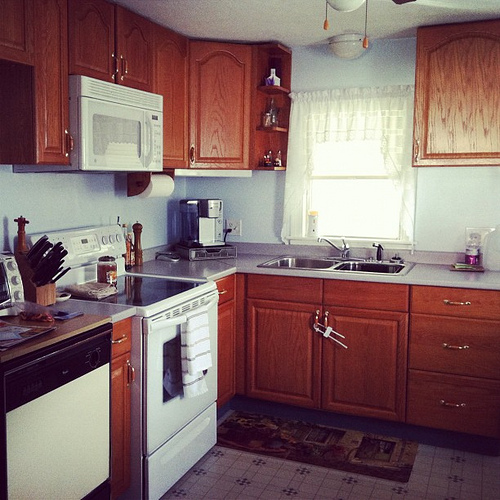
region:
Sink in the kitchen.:
[232, 217, 412, 317]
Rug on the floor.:
[211, 385, 415, 496]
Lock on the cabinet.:
[304, 294, 384, 383]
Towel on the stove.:
[163, 304, 243, 429]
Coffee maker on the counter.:
[163, 177, 258, 277]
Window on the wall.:
[260, 66, 457, 283]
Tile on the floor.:
[190, 431, 287, 493]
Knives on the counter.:
[13, 219, 79, 331]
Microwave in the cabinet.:
[54, 44, 283, 234]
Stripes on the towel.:
[155, 294, 261, 424]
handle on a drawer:
[435, 335, 472, 356]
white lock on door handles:
[307, 318, 352, 358]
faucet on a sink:
[314, 232, 370, 266]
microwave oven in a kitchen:
[62, 67, 170, 176]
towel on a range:
[175, 303, 218, 403]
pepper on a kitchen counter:
[129, 217, 149, 270]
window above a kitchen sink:
[276, 78, 427, 259]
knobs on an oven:
[97, 228, 127, 249]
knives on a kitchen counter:
[11, 233, 78, 308]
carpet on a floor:
[204, 404, 427, 490]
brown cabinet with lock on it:
[300, 298, 362, 350]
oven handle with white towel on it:
[166, 293, 231, 414]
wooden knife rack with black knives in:
[0, 247, 82, 322]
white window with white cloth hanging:
[293, 95, 408, 248]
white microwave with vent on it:
[23, 65, 179, 180]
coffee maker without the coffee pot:
[160, 187, 241, 277]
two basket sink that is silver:
[255, 220, 430, 283]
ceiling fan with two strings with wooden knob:
[323, 5, 393, 72]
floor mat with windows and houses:
[189, 368, 474, 493]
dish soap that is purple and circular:
[462, 218, 489, 275]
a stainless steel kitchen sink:
[260, 225, 411, 295]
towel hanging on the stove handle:
[162, 300, 229, 394]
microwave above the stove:
[68, 62, 175, 175]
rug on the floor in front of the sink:
[217, 390, 425, 495]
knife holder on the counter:
[15, 236, 73, 301]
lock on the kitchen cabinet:
[309, 301, 345, 357]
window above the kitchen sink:
[287, 81, 421, 246]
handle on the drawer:
[437, 334, 484, 362]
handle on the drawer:
[427, 392, 474, 428]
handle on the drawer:
[438, 293, 480, 317]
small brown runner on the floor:
[234, 404, 367, 463]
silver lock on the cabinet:
[287, 316, 365, 353]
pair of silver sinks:
[301, 255, 419, 267]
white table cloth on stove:
[177, 302, 237, 390]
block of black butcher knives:
[12, 212, 86, 304]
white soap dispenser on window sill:
[294, 207, 325, 240]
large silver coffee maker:
[172, 191, 242, 260]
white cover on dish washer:
[27, 406, 110, 461]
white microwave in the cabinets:
[63, 67, 191, 197]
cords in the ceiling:
[300, 5, 397, 57]